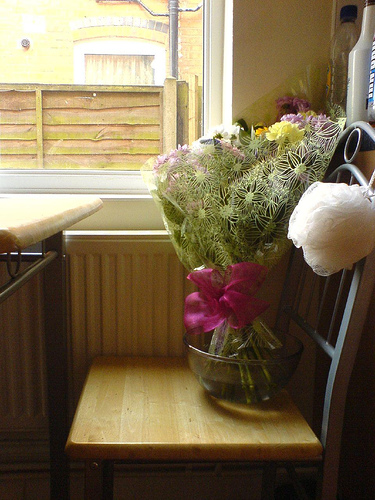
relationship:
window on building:
[76, 48, 163, 86] [3, 14, 214, 177]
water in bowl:
[188, 366, 298, 407] [170, 310, 312, 408]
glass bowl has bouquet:
[184, 325, 305, 403] [140, 58, 348, 403]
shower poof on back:
[286, 169, 373, 276] [279, 271, 374, 444]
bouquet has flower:
[140, 58, 348, 403] [265, 120, 305, 143]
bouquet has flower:
[140, 58, 348, 403] [277, 112, 305, 127]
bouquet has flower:
[140, 58, 348, 403] [276, 93, 308, 111]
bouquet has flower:
[140, 58, 348, 403] [209, 123, 244, 141]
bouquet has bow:
[140, 58, 348, 403] [183, 262, 271, 334]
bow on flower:
[180, 268, 259, 327] [268, 120, 300, 139]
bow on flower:
[180, 268, 259, 327] [280, 93, 303, 114]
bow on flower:
[180, 268, 259, 327] [315, 105, 341, 132]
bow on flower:
[180, 268, 259, 327] [221, 135, 247, 163]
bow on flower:
[180, 268, 259, 327] [192, 160, 217, 180]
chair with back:
[65, 121, 374, 498] [323, 124, 362, 428]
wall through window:
[1, 73, 203, 169] [0, 0, 203, 168]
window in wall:
[1, 14, 238, 234] [78, 236, 180, 327]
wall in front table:
[78, 236, 180, 327] [19, 174, 96, 251]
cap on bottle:
[337, 3, 361, 22] [330, 7, 356, 120]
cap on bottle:
[337, 3, 361, 22] [347, 0, 370, 123]